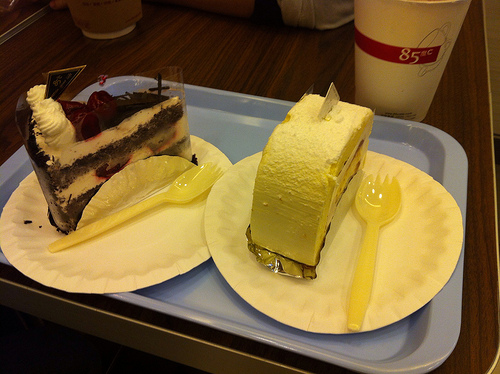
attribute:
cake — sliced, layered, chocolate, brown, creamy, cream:
[17, 87, 196, 231]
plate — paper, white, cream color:
[0, 131, 234, 294]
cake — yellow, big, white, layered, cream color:
[251, 90, 380, 267]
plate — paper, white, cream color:
[204, 148, 467, 334]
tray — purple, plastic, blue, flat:
[2, 75, 469, 374]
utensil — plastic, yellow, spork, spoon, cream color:
[348, 173, 399, 332]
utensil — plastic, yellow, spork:
[46, 160, 228, 254]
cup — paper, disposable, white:
[352, 0, 472, 122]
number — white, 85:
[398, 48, 419, 67]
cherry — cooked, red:
[89, 90, 116, 117]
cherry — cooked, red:
[73, 109, 102, 135]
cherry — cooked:
[59, 100, 86, 117]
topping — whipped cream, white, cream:
[27, 84, 75, 152]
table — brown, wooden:
[0, 4, 499, 374]